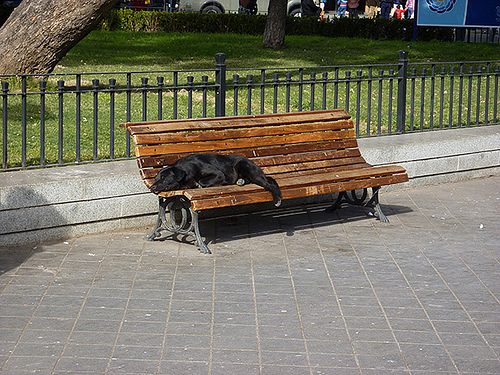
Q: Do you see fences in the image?
A: Yes, there is a fence.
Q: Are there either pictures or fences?
A: Yes, there is a fence.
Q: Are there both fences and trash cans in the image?
A: No, there is a fence but no trash cans.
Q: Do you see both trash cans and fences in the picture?
A: No, there is a fence but no trash cans.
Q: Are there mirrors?
A: No, there are no mirrors.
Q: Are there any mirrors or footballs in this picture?
A: No, there are no mirrors or footballs.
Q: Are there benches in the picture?
A: Yes, there is a bench.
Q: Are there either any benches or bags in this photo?
A: Yes, there is a bench.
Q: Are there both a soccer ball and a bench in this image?
A: No, there is a bench but no soccer balls.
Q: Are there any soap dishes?
A: No, there are no soap dishes.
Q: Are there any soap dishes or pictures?
A: No, there are no soap dishes or pictures.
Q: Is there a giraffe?
A: No, there are no giraffes.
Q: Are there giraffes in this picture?
A: No, there are no giraffes.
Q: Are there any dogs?
A: Yes, there is a dog.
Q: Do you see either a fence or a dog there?
A: Yes, there is a dog.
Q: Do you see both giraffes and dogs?
A: No, there is a dog but no giraffes.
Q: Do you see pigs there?
A: No, there are no pigs.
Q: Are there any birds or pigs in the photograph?
A: No, there are no pigs or birds.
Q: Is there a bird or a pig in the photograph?
A: No, there are no pigs or birds.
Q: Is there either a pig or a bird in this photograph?
A: No, there are no pigs or birds.